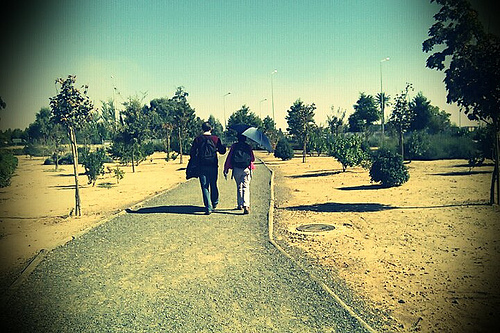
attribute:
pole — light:
[352, 41, 409, 176]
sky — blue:
[194, 12, 292, 51]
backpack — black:
[187, 132, 227, 158]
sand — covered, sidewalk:
[310, 203, 339, 222]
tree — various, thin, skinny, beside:
[336, 78, 433, 157]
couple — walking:
[193, 89, 263, 221]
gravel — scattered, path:
[93, 182, 130, 209]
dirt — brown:
[118, 171, 146, 198]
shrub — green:
[383, 161, 426, 185]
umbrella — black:
[231, 120, 274, 156]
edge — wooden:
[254, 162, 289, 272]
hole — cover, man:
[298, 213, 340, 241]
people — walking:
[161, 80, 297, 204]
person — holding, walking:
[202, 110, 276, 209]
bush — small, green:
[274, 112, 308, 173]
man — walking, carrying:
[187, 92, 237, 204]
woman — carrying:
[226, 122, 256, 192]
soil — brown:
[131, 167, 160, 185]